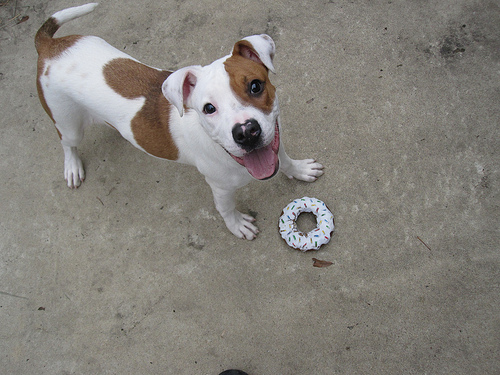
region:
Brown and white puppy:
[11, 45, 267, 257]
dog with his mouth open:
[224, 120, 286, 180]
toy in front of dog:
[261, 177, 328, 284]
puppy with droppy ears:
[167, 65, 199, 118]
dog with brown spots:
[76, 75, 183, 160]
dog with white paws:
[217, 215, 252, 245]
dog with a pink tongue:
[238, 137, 284, 189]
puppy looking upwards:
[173, 78, 325, 173]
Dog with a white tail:
[41, 4, 104, 33]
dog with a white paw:
[49, 140, 120, 220]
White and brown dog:
[28, 0, 329, 242]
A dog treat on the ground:
[276, 192, 338, 259]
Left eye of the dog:
[246, 74, 268, 99]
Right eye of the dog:
[200, 99, 219, 116]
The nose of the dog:
[231, 115, 264, 152]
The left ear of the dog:
[233, 30, 278, 77]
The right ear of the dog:
[157, 61, 202, 119]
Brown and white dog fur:
[85, 59, 131, 99]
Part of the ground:
[339, 19, 419, 106]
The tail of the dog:
[30, 0, 102, 55]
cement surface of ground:
[4, 2, 496, 369]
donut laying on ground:
[277, 195, 334, 251]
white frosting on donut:
[278, 196, 335, 251]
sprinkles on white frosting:
[278, 198, 335, 250]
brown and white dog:
[35, 2, 325, 240]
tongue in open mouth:
[229, 125, 282, 180]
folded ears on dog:
[161, 33, 276, 120]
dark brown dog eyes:
[202, 78, 266, 117]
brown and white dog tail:
[36, 0, 98, 49]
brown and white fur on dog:
[35, 3, 322, 238]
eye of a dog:
[247, 75, 268, 96]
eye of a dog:
[197, 98, 217, 123]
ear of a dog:
[154, 64, 202, 115]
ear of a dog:
[231, 30, 281, 81]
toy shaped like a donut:
[270, 189, 340, 257]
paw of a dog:
[224, 207, 263, 249]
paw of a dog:
[281, 150, 326, 188]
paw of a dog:
[60, 152, 88, 193]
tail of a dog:
[30, 0, 100, 53]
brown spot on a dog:
[94, 43, 187, 171]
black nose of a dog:
[227, 115, 267, 149]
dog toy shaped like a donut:
[272, 188, 339, 258]